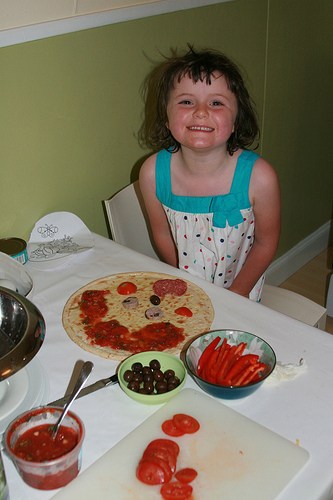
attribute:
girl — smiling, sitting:
[138, 41, 280, 303]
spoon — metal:
[51, 361, 93, 440]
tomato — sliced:
[172, 413, 199, 434]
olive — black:
[150, 359, 160, 371]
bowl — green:
[116, 351, 186, 405]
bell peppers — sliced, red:
[195, 335, 266, 388]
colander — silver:
[0, 285, 47, 383]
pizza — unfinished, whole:
[62, 272, 213, 360]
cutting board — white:
[47, 389, 308, 500]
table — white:
[0, 230, 332, 499]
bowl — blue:
[184, 329, 276, 399]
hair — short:
[148, 41, 262, 156]